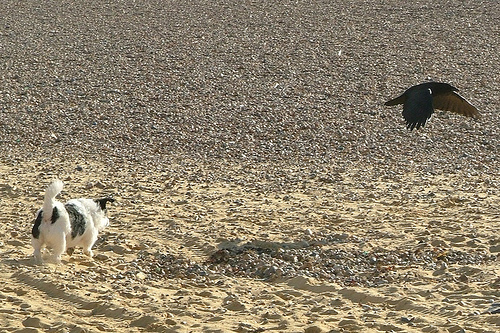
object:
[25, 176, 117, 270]
dog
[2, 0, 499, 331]
sand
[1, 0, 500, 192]
gravel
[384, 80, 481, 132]
bird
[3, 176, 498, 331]
tracks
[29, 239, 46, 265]
legs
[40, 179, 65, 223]
tail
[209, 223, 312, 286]
rocks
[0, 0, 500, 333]
ground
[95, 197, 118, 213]
ear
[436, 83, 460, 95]
head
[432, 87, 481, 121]
bird`s wing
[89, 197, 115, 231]
head